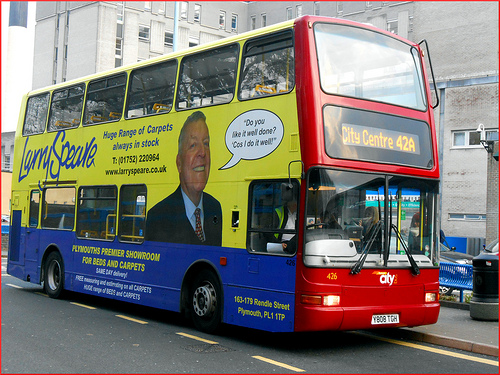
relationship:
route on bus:
[327, 113, 431, 166] [9, 15, 441, 337]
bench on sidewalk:
[443, 258, 474, 293] [403, 279, 497, 352]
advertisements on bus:
[16, 105, 292, 176] [9, 15, 441, 337]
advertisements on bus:
[66, 236, 166, 304] [9, 15, 441, 337]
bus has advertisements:
[9, 15, 441, 337] [16, 105, 292, 176]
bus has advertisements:
[9, 15, 441, 337] [66, 236, 166, 304]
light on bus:
[309, 282, 441, 327] [12, 6, 462, 357]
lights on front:
[323, 289, 440, 306] [298, 18, 440, 328]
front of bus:
[298, 18, 440, 328] [9, 15, 441, 337]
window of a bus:
[81, 70, 127, 122] [9, 15, 441, 337]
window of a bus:
[311, 27, 423, 112] [12, 6, 462, 357]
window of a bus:
[177, 44, 235, 109] [12, 6, 462, 357]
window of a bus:
[246, 177, 301, 255] [9, 15, 441, 337]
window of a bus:
[179, 53, 231, 103] [32, 75, 442, 317]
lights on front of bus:
[298, 290, 325, 306] [9, 15, 441, 337]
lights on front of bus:
[323, 294, 343, 306] [9, 15, 441, 337]